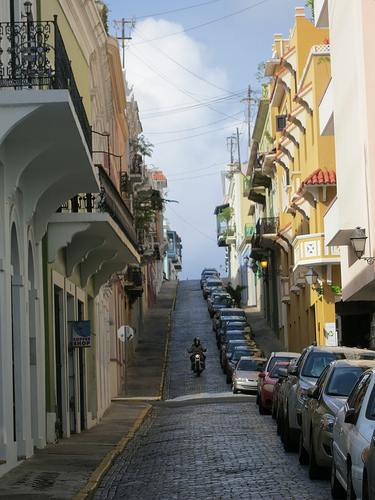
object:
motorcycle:
[186, 336, 209, 375]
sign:
[113, 318, 136, 348]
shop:
[0, 249, 155, 476]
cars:
[297, 357, 371, 480]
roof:
[149, 164, 170, 181]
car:
[330, 368, 375, 498]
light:
[242, 255, 250, 266]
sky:
[143, 0, 239, 129]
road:
[172, 265, 215, 338]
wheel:
[306, 421, 315, 477]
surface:
[168, 338, 188, 367]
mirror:
[342, 398, 363, 429]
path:
[139, 279, 183, 399]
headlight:
[318, 413, 333, 433]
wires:
[126, 14, 233, 100]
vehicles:
[205, 289, 238, 318]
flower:
[130, 198, 159, 226]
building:
[0, 18, 182, 480]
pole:
[118, 21, 128, 65]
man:
[182, 334, 209, 356]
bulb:
[258, 258, 269, 267]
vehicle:
[199, 267, 222, 279]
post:
[244, 82, 257, 146]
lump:
[165, 385, 231, 405]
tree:
[217, 206, 235, 236]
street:
[128, 279, 259, 496]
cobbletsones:
[95, 414, 272, 499]